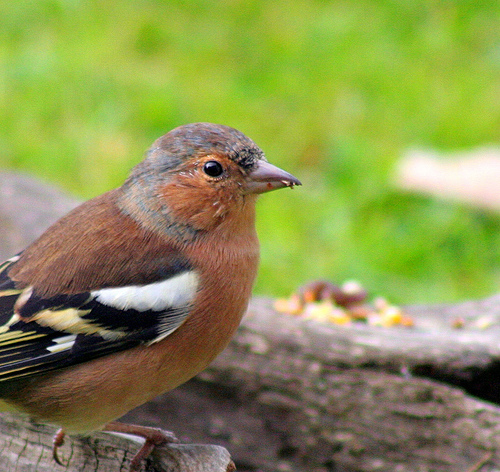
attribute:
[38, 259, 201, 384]
wings — black, white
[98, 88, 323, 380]
bird — orange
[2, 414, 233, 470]
rock — grey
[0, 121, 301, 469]
bird — yellow and orange, feathered, little, tiny, orange, small, black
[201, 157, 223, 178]
eye — small, round, black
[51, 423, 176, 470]
feet — orange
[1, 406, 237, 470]
bench — grey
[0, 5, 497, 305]
grass — green, dark green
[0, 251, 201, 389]
feathers — gold, black and white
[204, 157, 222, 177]
eye — black colored, black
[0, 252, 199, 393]
wings — black white and orange patterned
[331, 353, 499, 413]
hole — cracked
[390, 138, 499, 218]
foot — blurry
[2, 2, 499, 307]
leaves — blurry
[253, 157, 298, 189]
beak — gray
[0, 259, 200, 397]
wing — patterned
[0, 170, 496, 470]
ledge — wooden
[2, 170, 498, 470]
tree branch — large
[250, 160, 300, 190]
beak — grey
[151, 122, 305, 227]
head — grey